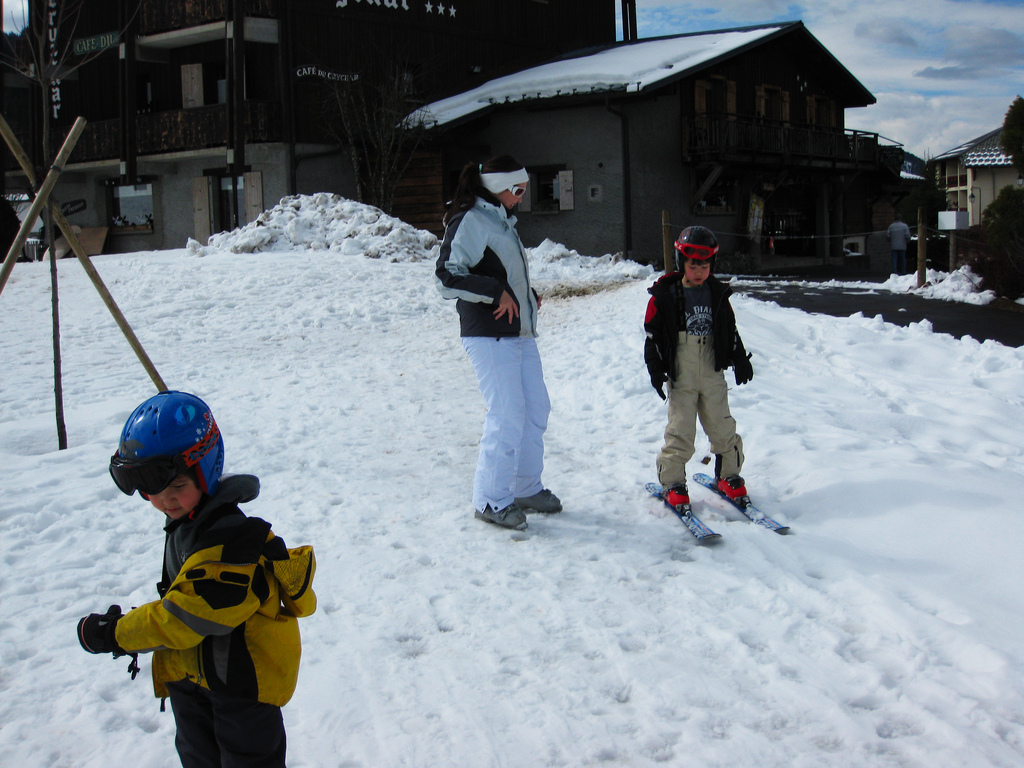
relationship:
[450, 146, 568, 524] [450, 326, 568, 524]
woman wearing pants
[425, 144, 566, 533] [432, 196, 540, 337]
woman wearing coat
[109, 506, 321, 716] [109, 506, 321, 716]
child wearing coat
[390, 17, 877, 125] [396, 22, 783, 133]
roof covered in snow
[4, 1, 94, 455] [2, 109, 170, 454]
sapling supported by poles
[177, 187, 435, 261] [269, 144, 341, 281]
pile of snow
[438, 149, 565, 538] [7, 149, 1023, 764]
person on snow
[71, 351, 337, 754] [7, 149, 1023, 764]
person on snow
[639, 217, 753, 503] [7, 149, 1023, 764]
person on snow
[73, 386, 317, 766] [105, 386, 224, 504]
child wearing helmet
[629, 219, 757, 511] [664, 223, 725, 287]
child wearing helmet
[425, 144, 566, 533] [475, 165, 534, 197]
woman wearing headband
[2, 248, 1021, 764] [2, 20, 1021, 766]
prints in snow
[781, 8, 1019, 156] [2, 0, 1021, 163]
cloud in sky